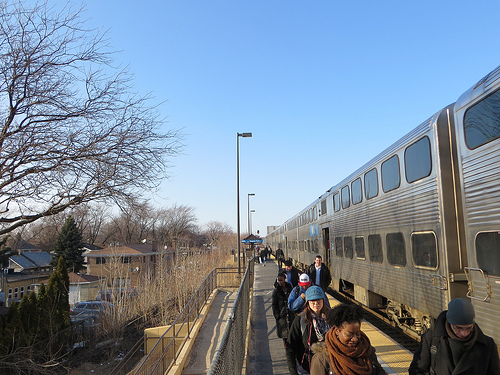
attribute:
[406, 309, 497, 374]
coat — dark 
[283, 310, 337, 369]
coat — dark 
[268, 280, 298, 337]
coat — dark 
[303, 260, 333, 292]
coat — dark 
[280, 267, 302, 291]
coat — dark 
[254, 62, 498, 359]
train — large, metal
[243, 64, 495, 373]
train — silver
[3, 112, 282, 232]
clouds — white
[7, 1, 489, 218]
sky — blue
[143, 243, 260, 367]
fence — gray, metal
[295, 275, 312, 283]
cap — red, white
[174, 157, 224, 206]
clouds — white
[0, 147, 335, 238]
clouds — white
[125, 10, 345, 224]
sky — blue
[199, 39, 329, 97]
clouds — white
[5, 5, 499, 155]
sky — blue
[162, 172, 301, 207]
clouds — white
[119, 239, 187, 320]
trees — bare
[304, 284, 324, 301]
cap — blue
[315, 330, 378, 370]
scarf — brown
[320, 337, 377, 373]
scarf — brown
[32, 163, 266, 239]
clouds — white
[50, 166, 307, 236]
clouds — white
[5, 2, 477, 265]
sky — blue